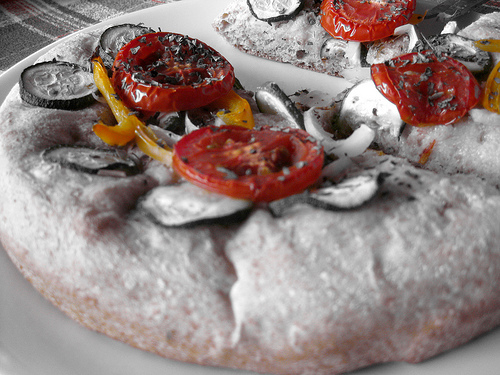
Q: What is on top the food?
A: Tomatoes.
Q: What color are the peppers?
A: Yellow.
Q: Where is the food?
A: On a plate.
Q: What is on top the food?
A: Tomatoes and peppers.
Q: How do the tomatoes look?
A: Cooked.